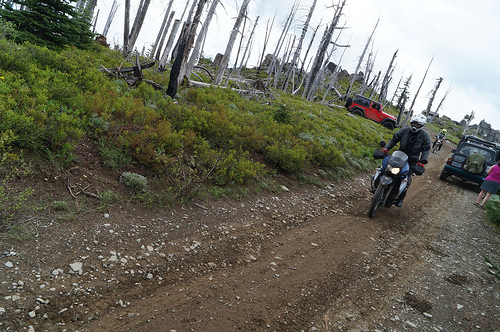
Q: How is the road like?
A: A brown dirt road.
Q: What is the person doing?
A: Riding a motorcycle down the road.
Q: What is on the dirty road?
A: Rocks.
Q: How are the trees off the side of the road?
A: Dead.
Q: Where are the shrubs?
A: Off the side of the road.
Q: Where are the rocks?
A: Along the road.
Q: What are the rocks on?
A: Dirt path.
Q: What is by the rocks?
A: Shrubs.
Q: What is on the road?
A: Dirt.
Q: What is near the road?
A: Shrubs.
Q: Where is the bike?
A: On the road.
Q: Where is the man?
A: On the bike.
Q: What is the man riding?
A: Bike.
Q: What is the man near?
A: Shrubs.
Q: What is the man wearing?
A: Helmet.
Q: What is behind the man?
A: Jeep.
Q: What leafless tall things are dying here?
A: Trees.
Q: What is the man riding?
A: Motorcycle.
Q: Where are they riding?
A: On a dirt trail.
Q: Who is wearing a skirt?
A: The woman by the Jeep.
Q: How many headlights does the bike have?
A: 1.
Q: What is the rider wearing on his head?
A: Helmet.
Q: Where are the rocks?
A: On the trail.